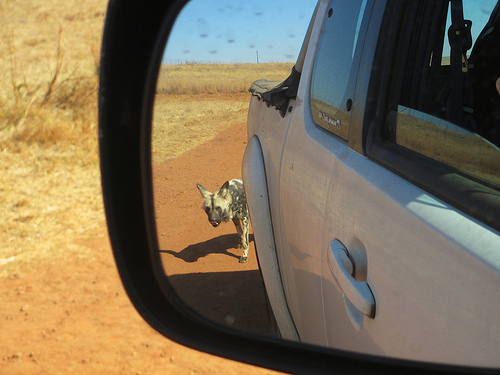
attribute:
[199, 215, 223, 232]
nose — black, dog's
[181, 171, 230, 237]
head — dog's, yellowish brown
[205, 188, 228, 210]
line — small, black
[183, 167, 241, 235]
head — dog's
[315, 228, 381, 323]
knob — car door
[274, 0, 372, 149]
window — small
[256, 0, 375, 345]
door — car's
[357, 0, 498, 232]
window — big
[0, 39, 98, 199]
weeds — yellow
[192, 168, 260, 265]
dog — black, yellowish, brown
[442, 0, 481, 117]
seatbelt — black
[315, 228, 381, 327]
door handle — silver, car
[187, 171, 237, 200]
ears — pointed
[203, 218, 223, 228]
nose — black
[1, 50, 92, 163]
plant — dead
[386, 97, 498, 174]
side window — partially open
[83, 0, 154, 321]
trim — black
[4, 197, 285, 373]
dirt road — red, clay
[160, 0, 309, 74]
sky — blue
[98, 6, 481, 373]
mirror — rear view, mounted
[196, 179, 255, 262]
canine — wild, spotted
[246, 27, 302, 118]
cover — black, plastic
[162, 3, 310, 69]
sky — flawless, blue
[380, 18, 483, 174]
window — open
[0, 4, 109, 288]
grass — dry, yellow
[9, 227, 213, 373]
road — brown, dirt, orange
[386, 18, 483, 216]
window — open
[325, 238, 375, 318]
handle — white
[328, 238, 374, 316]
handle — silver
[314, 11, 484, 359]
door — car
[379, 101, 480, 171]
window — rolled down, glass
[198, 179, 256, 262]
hyena — black, tan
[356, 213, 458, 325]
door — silver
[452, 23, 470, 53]
buckle — silver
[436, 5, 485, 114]
belt — seat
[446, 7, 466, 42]
belt — black, seat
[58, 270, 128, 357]
trail — deep, brown, dirt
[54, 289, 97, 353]
trail — dirt, tan, deep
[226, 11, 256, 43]
sky — bright, blue